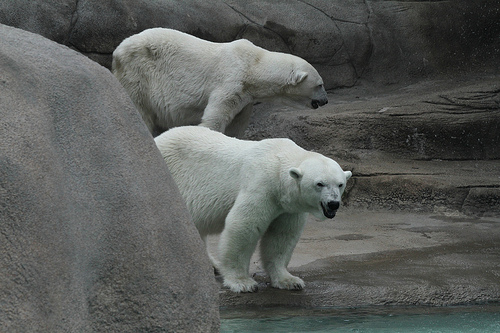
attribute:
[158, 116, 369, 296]
bear — white, looking, large, standing, walking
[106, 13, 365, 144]
polar bear — large, white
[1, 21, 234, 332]
boulder — large, gray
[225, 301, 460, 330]
water — small, clear, cold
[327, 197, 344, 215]
nose — black, big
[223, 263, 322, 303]
paws — large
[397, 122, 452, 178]
spots — white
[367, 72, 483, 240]
rock — gray, big, solid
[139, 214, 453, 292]
rocks — ladder-shaped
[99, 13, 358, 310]
bears — standing, white, standing up, big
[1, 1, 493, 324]
area — rocky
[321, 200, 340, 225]
mouth — open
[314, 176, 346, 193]
eyes — small